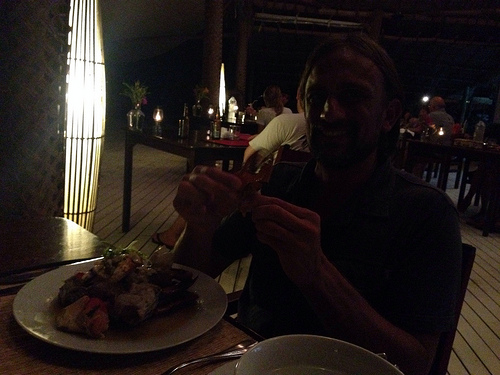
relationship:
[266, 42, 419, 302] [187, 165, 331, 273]
man has hands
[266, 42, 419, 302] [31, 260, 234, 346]
man has a plate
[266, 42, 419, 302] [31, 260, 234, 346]
man nearest plate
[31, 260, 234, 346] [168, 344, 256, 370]
plate has utensils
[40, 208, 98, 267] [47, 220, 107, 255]
table has reflections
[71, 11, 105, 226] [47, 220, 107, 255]
light has reflections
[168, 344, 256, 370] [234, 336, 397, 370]
utensil near bowl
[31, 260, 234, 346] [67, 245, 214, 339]
plate has food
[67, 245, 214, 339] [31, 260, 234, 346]
food on plate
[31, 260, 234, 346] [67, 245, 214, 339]
plate nearest has food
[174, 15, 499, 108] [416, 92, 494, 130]
background has people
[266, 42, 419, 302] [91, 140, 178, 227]
man near floor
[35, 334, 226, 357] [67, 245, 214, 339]
white plate has food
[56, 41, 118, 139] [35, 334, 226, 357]
bright light white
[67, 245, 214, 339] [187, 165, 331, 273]
food in hands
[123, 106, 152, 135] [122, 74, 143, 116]
vase has plant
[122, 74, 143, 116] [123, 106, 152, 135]
plant in vase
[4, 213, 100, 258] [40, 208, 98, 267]
brown wood table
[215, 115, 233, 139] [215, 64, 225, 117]
glass with candle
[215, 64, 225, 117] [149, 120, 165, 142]
candle in wine glass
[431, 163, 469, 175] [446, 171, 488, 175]
carpet beige and black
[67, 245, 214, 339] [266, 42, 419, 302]
food eaten by man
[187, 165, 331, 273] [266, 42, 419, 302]
hands of man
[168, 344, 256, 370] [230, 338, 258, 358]
silver utensil handle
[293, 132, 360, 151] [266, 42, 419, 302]
beard on man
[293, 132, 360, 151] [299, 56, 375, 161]
beard on mans face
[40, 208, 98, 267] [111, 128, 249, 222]
table of wood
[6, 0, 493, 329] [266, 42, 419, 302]
restaurant has man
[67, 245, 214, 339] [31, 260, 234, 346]
food on white plate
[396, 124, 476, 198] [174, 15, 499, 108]
tables of people in background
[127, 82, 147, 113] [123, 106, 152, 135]
flower in vase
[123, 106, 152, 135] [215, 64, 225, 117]
vase has candle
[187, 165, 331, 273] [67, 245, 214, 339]
hands holding food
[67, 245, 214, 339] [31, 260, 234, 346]
food on dish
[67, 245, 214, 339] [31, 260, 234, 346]
food full on dish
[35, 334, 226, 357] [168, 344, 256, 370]
white dish has utensils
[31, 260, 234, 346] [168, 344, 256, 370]
dish has utensils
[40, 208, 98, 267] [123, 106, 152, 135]
table has vase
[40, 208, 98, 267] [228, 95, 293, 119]
table with couple